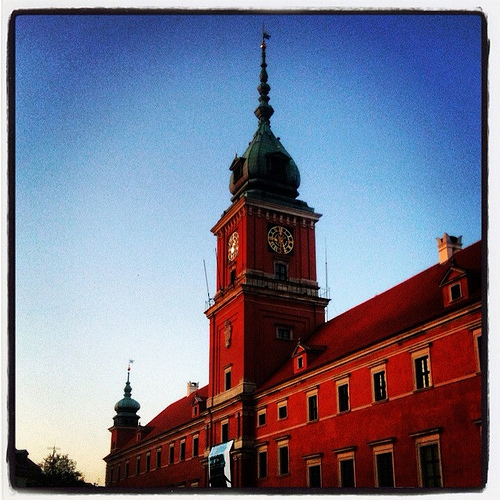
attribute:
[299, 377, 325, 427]
window — rectangular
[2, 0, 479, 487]
blue sky — clear-blue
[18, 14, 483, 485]
photograph — grainy, color, soaked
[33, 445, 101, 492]
tree — green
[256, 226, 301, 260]
clock — white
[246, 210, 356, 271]
clock — round, white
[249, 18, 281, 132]
turret — large, green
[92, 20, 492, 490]
building — big, long, red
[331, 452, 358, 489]
window — rectangular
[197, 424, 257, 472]
banner — white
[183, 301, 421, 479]
building — red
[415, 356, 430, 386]
courtain — white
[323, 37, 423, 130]
sky — blue, clear, sunny